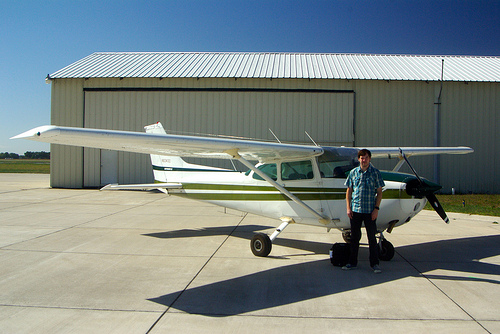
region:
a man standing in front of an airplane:
[332, 139, 392, 259]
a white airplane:
[27, 100, 492, 267]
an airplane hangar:
[46, 50, 499, 184]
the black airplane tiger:
[243, 225, 287, 260]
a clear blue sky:
[12, 54, 42, 111]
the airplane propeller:
[392, 136, 478, 228]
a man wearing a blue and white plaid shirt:
[343, 152, 398, 252]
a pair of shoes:
[335, 255, 405, 277]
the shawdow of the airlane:
[145, 210, 493, 307]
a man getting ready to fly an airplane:
[8, 88, 458, 263]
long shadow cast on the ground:
[105, 272, 257, 329]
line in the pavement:
[118, 228, 268, 297]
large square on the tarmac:
[167, 232, 473, 330]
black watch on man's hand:
[374, 195, 381, 215]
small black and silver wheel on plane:
[239, 230, 279, 259]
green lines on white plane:
[180, 170, 286, 211]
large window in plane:
[291, 149, 353, 181]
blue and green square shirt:
[338, 165, 387, 215]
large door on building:
[75, 53, 482, 183]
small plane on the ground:
[1, 65, 493, 266]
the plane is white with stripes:
[146, 136, 412, 270]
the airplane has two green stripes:
[178, 166, 375, 209]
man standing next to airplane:
[340, 156, 411, 273]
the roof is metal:
[97, 41, 482, 78]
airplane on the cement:
[130, 125, 480, 331]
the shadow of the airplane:
[175, 206, 448, 329]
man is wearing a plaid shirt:
[340, 150, 393, 243]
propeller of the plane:
[395, 138, 475, 224]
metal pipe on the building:
[421, 74, 478, 196]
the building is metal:
[33, 89, 488, 124]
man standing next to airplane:
[343, 146, 384, 257]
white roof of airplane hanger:
[45, 36, 495, 87]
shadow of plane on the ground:
[143, 220, 498, 319]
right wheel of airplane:
[247, 230, 270, 256]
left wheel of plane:
[335, 221, 358, 239]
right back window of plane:
[246, 158, 277, 183]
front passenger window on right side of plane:
[278, 156, 315, 179]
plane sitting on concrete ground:
[7, 118, 477, 249]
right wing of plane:
[10, 120, 315, 151]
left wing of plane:
[358, 142, 477, 157]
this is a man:
[334, 147, 386, 278]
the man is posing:
[336, 148, 391, 273]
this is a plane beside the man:
[129, 140, 324, 245]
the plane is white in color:
[234, 141, 317, 218]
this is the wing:
[60, 112, 255, 167]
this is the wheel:
[244, 230, 281, 261]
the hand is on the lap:
[366, 187, 386, 223]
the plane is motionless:
[132, 135, 323, 254]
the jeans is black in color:
[347, 223, 374, 259]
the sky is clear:
[270, 10, 307, 49]